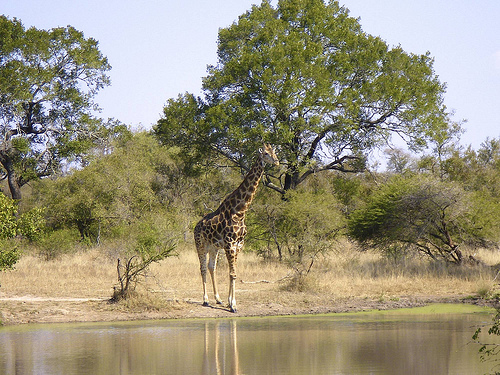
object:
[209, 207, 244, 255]
patterns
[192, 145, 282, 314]
giraffe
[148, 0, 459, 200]
green tree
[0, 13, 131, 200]
green tree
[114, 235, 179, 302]
tree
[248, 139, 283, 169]
head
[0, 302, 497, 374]
water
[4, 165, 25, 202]
tree trunk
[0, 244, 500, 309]
grass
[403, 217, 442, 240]
branch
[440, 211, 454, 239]
branch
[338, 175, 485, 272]
tree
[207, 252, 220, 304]
back leg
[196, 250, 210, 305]
back leg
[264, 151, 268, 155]
eye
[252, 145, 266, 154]
giraffe ear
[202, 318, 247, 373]
reflection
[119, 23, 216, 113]
sky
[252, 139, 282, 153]
horns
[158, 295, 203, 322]
dirt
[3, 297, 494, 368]
stream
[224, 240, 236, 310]
leg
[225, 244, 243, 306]
leg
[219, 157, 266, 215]
neck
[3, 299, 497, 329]
moss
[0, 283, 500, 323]
edge